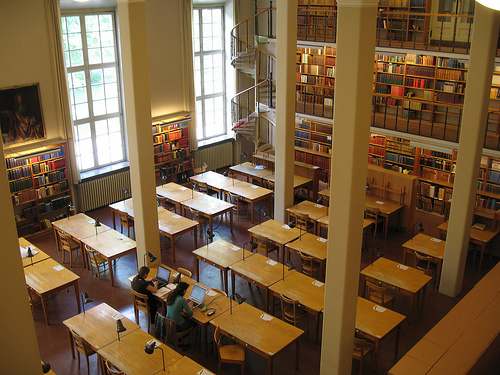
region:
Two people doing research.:
[123, 261, 216, 323]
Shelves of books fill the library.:
[366, 57, 461, 174]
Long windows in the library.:
[68, 4, 120, 184]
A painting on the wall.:
[5, 65, 54, 155]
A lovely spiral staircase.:
[220, 5, 274, 152]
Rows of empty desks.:
[162, 153, 267, 233]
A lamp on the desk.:
[103, 309, 135, 345]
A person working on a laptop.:
[127, 242, 169, 309]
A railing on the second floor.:
[370, 98, 460, 125]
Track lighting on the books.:
[5, 133, 66, 176]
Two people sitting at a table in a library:
[130, 264, 194, 329]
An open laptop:
[152, 263, 172, 288]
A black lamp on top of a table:
[92, 217, 102, 235]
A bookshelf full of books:
[5, 140, 81, 238]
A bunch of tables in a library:
[0, 159, 499, 373]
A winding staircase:
[227, 6, 275, 152]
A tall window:
[57, 6, 131, 181]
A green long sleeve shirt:
[164, 295, 194, 327]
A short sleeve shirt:
[131, 277, 154, 301]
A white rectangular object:
[257, 312, 274, 323]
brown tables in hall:
[52, 178, 416, 336]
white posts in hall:
[245, 3, 325, 233]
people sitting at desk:
[140, 246, 197, 327]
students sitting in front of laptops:
[131, 260, 220, 322]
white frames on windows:
[56, 1, 145, 163]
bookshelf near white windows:
[138, 113, 210, 192]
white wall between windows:
[140, 14, 189, 84]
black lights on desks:
[108, 317, 155, 369]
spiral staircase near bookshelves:
[228, 15, 284, 160]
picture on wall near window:
[1, 80, 61, 150]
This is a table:
[206, 298, 311, 370]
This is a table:
[79, 225, 149, 273]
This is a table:
[188, 221, 252, 286]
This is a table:
[361, 252, 433, 303]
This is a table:
[346, 293, 401, 350]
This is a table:
[269, 273, 345, 340]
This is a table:
[235, 250, 296, 298]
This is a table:
[175, 227, 253, 280]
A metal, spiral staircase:
[232, 3, 274, 160]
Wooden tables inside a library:
[17, 160, 487, 372]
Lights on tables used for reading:
[112, 320, 167, 372]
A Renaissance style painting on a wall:
[1, 83, 46, 147]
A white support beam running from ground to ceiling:
[117, 0, 160, 266]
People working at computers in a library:
[132, 268, 192, 337]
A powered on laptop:
[189, 287, 207, 306]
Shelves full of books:
[6, 0, 498, 239]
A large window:
[57, 7, 127, 173]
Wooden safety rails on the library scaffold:
[292, 82, 497, 149]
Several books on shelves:
[14, 163, 39, 186]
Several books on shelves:
[12, 161, 58, 200]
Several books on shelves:
[22, 163, 59, 199]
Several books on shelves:
[11, 164, 53, 204]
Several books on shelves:
[16, 161, 63, 201]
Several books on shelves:
[15, 163, 57, 195]